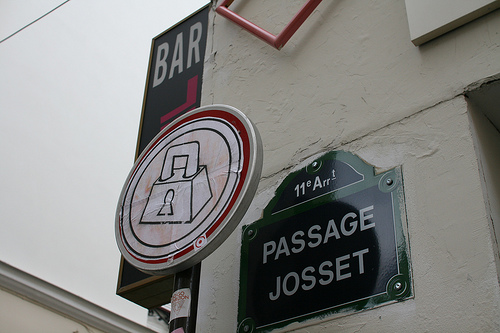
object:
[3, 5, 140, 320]
cloud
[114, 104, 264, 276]
sign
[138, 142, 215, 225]
lock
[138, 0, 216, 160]
sign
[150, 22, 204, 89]
bar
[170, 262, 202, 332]
pole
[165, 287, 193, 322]
sticker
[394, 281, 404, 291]
bolt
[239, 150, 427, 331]
sign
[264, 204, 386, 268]
passage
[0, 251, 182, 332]
roof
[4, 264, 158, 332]
gutter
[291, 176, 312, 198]
11e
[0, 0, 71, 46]
wire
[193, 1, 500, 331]
building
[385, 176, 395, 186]
fastener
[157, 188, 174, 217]
keyhole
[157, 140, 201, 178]
handle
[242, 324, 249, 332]
screw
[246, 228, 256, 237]
screw